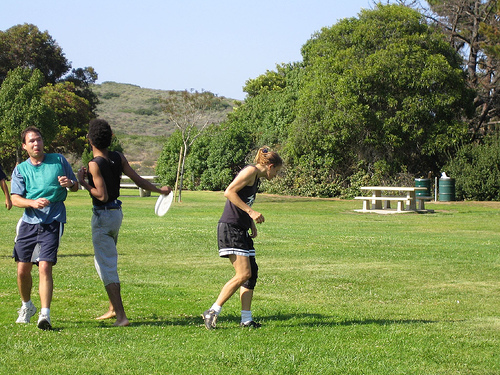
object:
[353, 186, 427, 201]
table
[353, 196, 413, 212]
bench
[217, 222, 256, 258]
shorts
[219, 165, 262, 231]
shirt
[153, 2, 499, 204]
trees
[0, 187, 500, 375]
grass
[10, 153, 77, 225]
shirt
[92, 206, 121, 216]
belt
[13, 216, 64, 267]
shorts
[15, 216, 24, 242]
stripe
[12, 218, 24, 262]
side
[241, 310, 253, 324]
socks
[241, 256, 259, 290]
brace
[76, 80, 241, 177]
hill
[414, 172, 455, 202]
garbage cans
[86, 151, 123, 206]
shirt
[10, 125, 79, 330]
guy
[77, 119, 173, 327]
female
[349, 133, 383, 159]
branches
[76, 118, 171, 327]
man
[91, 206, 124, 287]
capris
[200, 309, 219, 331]
shoes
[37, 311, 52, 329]
shoes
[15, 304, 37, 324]
shoes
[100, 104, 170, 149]
wall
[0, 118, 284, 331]
people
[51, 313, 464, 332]
shadow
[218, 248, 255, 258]
white strips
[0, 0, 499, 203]
green leaves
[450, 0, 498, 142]
branches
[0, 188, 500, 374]
field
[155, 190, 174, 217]
frisbee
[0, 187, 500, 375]
ground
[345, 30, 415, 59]
branches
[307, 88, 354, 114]
branches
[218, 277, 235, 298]
calf